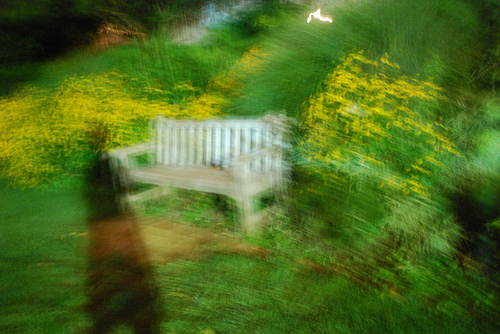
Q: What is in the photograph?
A: A bench.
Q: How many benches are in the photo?
A: One.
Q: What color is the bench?
A: White.